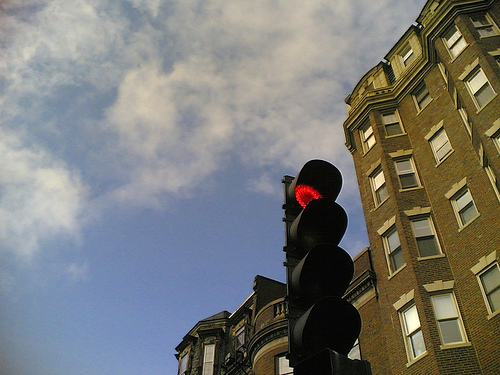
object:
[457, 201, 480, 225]
window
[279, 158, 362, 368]
traffic light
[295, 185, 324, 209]
light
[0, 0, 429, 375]
sky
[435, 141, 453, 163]
window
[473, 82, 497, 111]
window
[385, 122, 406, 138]
window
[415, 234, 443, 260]
window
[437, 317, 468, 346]
window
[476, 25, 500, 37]
windows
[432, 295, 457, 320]
curtains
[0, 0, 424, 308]
clouds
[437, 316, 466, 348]
frame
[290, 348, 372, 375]
pole